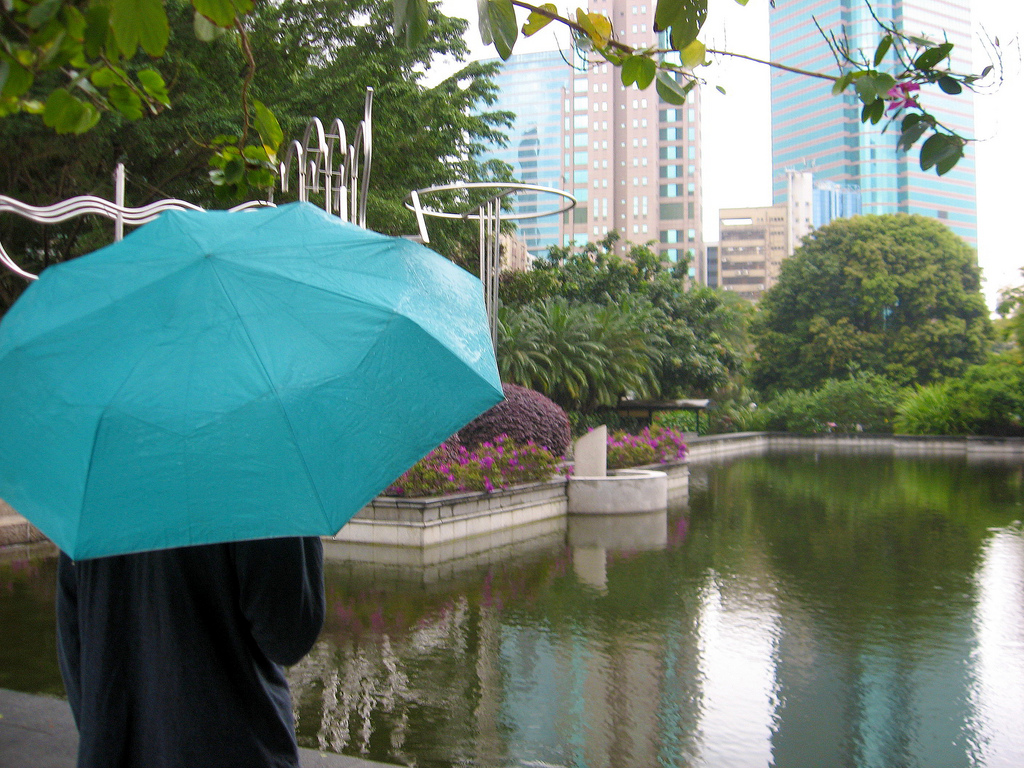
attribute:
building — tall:
[599, 108, 705, 229]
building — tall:
[591, 35, 730, 172]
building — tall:
[649, 119, 710, 284]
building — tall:
[502, 95, 686, 191]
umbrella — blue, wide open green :
[10, 198, 507, 566]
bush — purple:
[457, 380, 576, 460]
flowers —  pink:
[606, 423, 695, 454]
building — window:
[555, 102, 599, 128]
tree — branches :
[0, 7, 960, 163]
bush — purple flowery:
[548, 214, 991, 375]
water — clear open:
[630, 541, 944, 764]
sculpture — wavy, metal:
[0, 162, 284, 312]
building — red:
[714, 203, 788, 307]